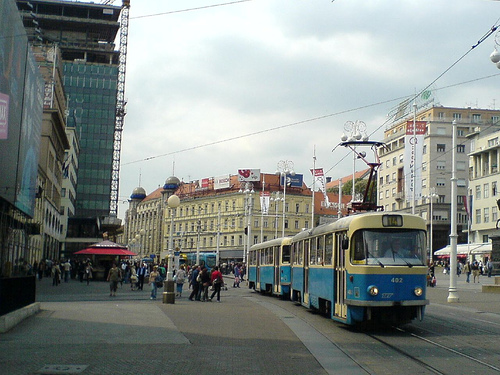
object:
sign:
[259, 197, 270, 217]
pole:
[281, 166, 288, 237]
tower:
[109, 64, 121, 223]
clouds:
[233, 0, 411, 84]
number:
[388, 218, 392, 224]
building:
[242, 166, 311, 278]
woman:
[147, 265, 164, 301]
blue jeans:
[149, 282, 160, 298]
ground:
[374, 139, 397, 171]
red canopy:
[74, 240, 136, 256]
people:
[231, 261, 241, 289]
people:
[198, 266, 211, 303]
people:
[49, 262, 60, 287]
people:
[471, 260, 482, 286]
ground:
[324, 171, 353, 192]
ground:
[401, 170, 426, 189]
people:
[208, 267, 224, 302]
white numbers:
[391, 277, 396, 283]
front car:
[287, 210, 430, 329]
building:
[2, 1, 43, 283]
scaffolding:
[110, 1, 127, 234]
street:
[3, 265, 495, 372]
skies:
[116, 0, 500, 189]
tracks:
[325, 332, 455, 375]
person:
[106, 259, 124, 300]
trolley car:
[289, 208, 436, 333]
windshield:
[351, 227, 431, 268]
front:
[347, 211, 426, 325]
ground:
[0, 261, 497, 375]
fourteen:
[382, 214, 401, 228]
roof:
[136, 170, 312, 202]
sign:
[236, 168, 261, 183]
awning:
[433, 238, 497, 258]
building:
[463, 129, 497, 279]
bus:
[233, 209, 430, 332]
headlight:
[413, 287, 425, 299]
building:
[63, 0, 122, 250]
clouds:
[165, 92, 298, 156]